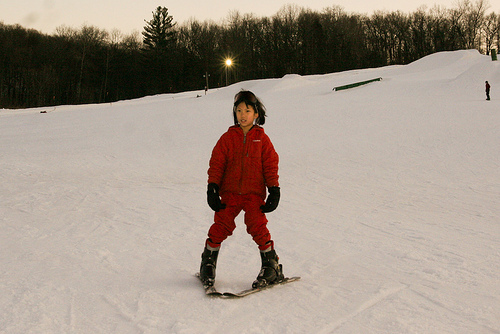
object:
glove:
[260, 187, 282, 214]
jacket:
[207, 124, 279, 196]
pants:
[206, 194, 274, 251]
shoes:
[199, 248, 219, 287]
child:
[195, 88, 301, 298]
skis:
[195, 273, 301, 298]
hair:
[232, 90, 268, 126]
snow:
[0, 49, 500, 334]